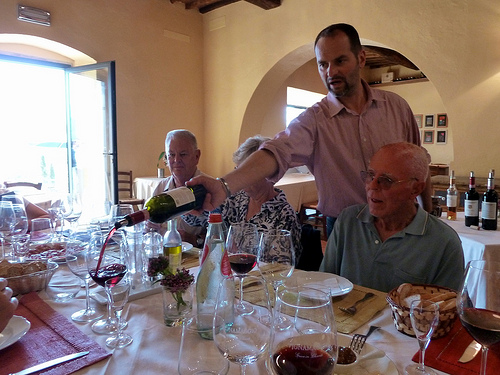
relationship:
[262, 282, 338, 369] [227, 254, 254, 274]
glass of wine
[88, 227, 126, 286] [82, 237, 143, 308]
wine on glass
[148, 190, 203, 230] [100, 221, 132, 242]
bottle on rim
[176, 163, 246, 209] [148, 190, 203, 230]
hand on bottle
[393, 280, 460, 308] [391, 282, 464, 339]
sticks in basket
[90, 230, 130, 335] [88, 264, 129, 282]
glass of wine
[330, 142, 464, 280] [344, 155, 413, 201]
man wearing glasses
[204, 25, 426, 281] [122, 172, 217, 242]
man holding wine bottle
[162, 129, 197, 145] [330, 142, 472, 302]
hair on man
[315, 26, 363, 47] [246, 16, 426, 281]
hair on man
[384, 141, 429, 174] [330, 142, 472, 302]
hair on man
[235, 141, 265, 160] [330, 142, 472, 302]
hair on man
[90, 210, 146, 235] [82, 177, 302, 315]
wine in bottles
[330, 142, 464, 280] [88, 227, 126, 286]
man pouring wine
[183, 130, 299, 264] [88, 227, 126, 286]
someone pouring wine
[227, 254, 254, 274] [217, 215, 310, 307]
wine in glass